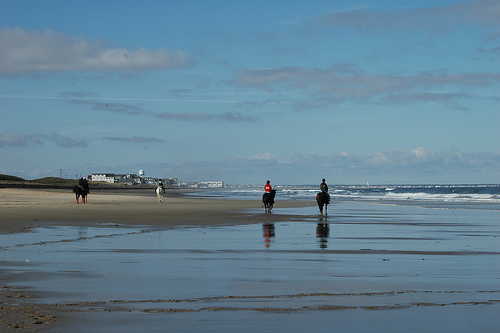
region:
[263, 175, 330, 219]
two people riding horses on the beach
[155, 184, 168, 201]
a white horse on the beach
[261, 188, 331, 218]
two black horses on the beach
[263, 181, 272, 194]
person wearing a red shirt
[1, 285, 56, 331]
footprints on the wet sand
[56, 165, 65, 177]
a telephone pole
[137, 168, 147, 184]
a white water tower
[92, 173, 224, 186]
a row of buildings on the beach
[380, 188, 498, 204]
gentle surf crashing on the sand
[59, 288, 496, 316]
skid marks on the wet sand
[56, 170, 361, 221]
the people riding horses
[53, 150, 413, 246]
the people riding horses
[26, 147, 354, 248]
horses are the beach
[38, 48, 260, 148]
gray and white clouds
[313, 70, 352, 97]
part of a cloud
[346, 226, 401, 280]
part of a water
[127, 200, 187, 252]
edge of a shore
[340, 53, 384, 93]
part of a cloud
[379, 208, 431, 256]
part of a water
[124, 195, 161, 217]
part of a beach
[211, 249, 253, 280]
part of a water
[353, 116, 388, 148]
part of the sky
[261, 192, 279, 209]
part of a horse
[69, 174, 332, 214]
four horses on the beach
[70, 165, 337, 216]
four people riding horses on the beach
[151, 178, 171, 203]
white horse walking down beach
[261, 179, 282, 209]
person wearing red shirt riding down beach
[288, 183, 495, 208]
wave crushing on to the shore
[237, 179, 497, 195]
fishing pier in the distance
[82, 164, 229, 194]
beach houses in the distance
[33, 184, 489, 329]
wet sand on the beach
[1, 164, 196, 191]
dunes along the beach sand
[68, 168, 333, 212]
three black horses walking down beach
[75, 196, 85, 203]
a few bright red bandages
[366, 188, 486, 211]
a wave crashing on the beach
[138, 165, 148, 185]
a distant water tower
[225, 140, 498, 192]
a mountain range in the background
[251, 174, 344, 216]
a few people on horseback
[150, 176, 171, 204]
a person riding a horse on the beach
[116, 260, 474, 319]
some tracks in the sand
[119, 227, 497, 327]
some wet sand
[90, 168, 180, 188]
a few distant white buildings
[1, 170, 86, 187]
a few sloping hills